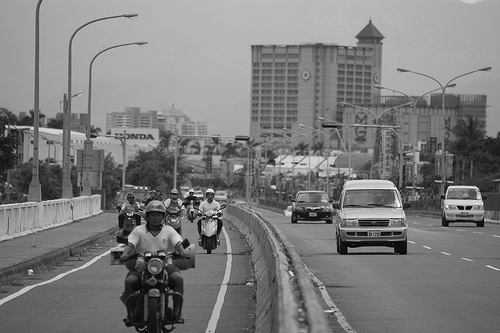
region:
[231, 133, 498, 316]
vehicles are travelling on the road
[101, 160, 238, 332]
motorbikes are on the sideway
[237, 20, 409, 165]
the house has windows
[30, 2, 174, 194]
the street lights are off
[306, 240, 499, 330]
the tarmac is black with white stripes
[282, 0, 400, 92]
the house has a dome on top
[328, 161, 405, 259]
the car is white in colour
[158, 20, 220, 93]
the sky is daark with clouds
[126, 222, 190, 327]
the pullover is white in colour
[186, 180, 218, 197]
he helmet is white in colour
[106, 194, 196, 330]
a man on motorcycle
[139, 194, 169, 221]
man wearing a helmet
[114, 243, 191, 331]
man riding motorcycle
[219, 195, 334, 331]
concrete barrier separates roads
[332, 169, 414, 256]
small van driving in right lane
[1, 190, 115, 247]
concrete railing on sidewalk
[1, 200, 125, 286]
sidewalk to the right of the lane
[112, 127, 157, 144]
honda is written on building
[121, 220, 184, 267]
rider is wearing white shirt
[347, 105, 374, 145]
mg written on side of building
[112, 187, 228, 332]
group of people on motorbikes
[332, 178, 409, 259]
a car on the street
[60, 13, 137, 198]
a tall metal light post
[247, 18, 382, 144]
a large building with windows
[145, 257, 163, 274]
headlight on a bike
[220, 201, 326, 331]
a concrete barrier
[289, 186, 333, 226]
a small car on the street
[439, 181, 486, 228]
suv on the street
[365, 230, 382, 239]
license plate on a car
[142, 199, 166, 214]
helmet on a man's head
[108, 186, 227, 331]
the people on the motorcycles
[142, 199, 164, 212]
the helmet on the man's head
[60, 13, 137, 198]
the street light on the side of the road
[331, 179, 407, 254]
the vehicle on the road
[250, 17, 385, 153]
the large building in the background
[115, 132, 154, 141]
the word HONDA on the building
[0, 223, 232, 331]
the lines on the road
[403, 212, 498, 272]
the dashed lines on the road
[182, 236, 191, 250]
the mirror on the motorcycle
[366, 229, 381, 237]
the license plate on the vehicle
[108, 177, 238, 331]
many men wearing helmets riding motorcycles down the road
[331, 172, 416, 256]
white suv driving down the road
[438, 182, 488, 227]
white vehicle driving down the road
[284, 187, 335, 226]
black car driving down the road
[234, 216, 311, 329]
concrete divider between two lanes of traffic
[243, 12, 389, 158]
a very large building in the distance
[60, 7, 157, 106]
two tall streetlights along side of the road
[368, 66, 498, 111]
several curved streetlights over the road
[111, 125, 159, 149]
Honda building in the distance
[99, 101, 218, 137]
several tall buildings in the distance